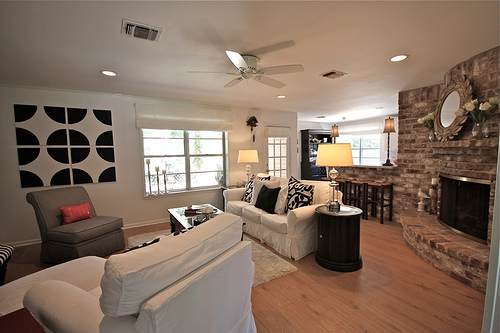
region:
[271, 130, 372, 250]
table lamp on table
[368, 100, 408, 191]
tall lamp on counter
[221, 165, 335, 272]
white couch in living room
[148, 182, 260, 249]
table in living room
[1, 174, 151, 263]
grey chair in living room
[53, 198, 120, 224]
orange pillow on chair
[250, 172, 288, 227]
black pillow on chair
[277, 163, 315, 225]
black and white pillow on couch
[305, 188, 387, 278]
round end table in living room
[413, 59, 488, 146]
round framed mirror on wall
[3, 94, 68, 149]
Black and white picture on the wall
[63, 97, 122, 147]
Black and white picture on the wall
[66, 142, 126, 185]
Black and white picture on the wall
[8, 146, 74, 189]
Black and white picture on the wall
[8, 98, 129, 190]
Black and white picture on the wall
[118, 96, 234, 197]
Whtite window with silver bard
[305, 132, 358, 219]
Clear and silver lamp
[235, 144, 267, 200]
Clear and silver lamp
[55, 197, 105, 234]
Yellow pellow on a chair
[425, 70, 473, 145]
Silver mirror in the wall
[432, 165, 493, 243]
fire place in brick wall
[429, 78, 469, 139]
brick mirror on wall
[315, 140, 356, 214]
lamp on end table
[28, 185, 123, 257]
grey lounge chair in room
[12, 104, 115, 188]
black and white picture on wall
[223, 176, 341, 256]
white fabric sofa in room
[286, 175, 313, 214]
black and white pillow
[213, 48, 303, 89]
white fan on ceiling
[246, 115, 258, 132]
coocoo clock on wall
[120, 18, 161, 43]
air vent on ceiling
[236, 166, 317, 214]
Black and white pillows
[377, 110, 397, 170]
Long table lamp with shade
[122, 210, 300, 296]
White area rug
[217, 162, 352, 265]
White couch with pillows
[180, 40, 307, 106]
White ceiling fan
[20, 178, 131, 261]
Grey chair with red pillow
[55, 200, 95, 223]
Red long throw pillow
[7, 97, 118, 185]
Black and white wall art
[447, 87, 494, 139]
White roses in a vase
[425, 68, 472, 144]
Round decorative mirror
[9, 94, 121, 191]
balck and white art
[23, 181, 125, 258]
chair with a red pillow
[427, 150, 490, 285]
brick fireplace with a screen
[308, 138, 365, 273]
end table with a lamp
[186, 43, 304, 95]
white ceiling fan with five blades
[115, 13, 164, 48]
ceiling vent with slates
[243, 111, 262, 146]
cuckoo clock on a wall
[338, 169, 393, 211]
bar stools in a row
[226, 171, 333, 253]
white couch with pillows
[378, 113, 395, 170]
tall lamp with shade